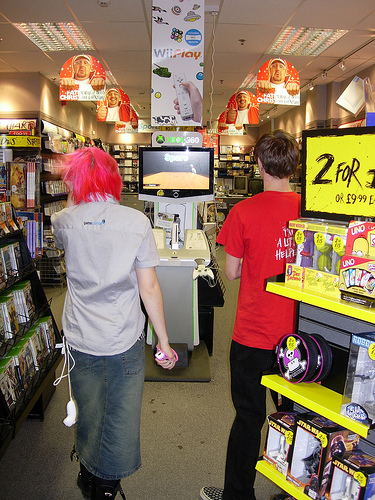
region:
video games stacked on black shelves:
[0, 236, 58, 410]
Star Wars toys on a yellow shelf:
[261, 409, 374, 498]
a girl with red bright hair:
[58, 143, 120, 203]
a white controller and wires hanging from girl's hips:
[51, 335, 74, 425]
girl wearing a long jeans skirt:
[60, 319, 143, 478]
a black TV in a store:
[139, 144, 214, 199]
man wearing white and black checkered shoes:
[198, 485, 227, 498]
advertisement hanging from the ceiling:
[150, 1, 203, 128]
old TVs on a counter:
[231, 174, 262, 195]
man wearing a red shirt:
[218, 189, 296, 351]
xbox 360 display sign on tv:
[151, 130, 198, 142]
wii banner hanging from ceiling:
[150, 0, 205, 125]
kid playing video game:
[43, 143, 174, 439]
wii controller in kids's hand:
[152, 342, 176, 368]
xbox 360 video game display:
[0, 229, 61, 409]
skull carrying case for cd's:
[272, 330, 328, 385]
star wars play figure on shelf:
[283, 421, 343, 496]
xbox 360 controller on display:
[190, 262, 214, 278]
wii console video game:
[168, 220, 177, 250]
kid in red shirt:
[216, 130, 303, 358]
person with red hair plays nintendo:
[45, 137, 136, 228]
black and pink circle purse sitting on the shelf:
[269, 329, 334, 387]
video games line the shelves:
[3, 277, 34, 417]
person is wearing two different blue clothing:
[63, 197, 159, 482]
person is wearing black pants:
[229, 335, 263, 498]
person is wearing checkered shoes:
[197, 474, 228, 498]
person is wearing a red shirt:
[219, 181, 294, 353]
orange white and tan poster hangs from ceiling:
[252, 51, 306, 113]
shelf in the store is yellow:
[261, 360, 372, 426]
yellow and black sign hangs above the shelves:
[301, 122, 373, 232]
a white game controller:
[57, 396, 83, 428]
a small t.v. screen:
[136, 142, 214, 195]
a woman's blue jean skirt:
[69, 337, 147, 478]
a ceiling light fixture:
[267, 25, 340, 60]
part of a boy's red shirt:
[215, 188, 307, 353]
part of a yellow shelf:
[257, 366, 367, 449]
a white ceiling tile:
[222, 2, 290, 29]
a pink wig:
[61, 146, 124, 203]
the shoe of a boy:
[197, 480, 222, 499]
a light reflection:
[41, 86, 51, 117]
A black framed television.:
[137, 147, 213, 193]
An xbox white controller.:
[189, 260, 214, 283]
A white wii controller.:
[155, 345, 170, 364]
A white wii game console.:
[168, 218, 180, 249]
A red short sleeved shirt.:
[215, 189, 299, 349]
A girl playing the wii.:
[55, 147, 177, 497]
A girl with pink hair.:
[46, 141, 180, 496]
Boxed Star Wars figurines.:
[255, 408, 372, 499]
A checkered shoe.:
[197, 480, 222, 498]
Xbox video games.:
[0, 279, 56, 413]